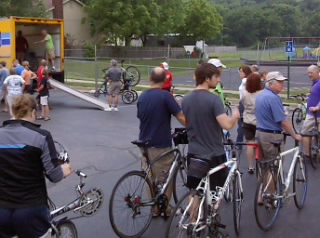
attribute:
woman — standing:
[1, 93, 72, 236]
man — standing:
[103, 58, 125, 113]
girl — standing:
[33, 70, 50, 122]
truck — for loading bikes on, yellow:
[0, 15, 66, 91]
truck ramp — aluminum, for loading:
[48, 77, 108, 111]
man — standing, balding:
[299, 64, 319, 161]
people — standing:
[134, 58, 320, 238]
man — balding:
[135, 66, 185, 220]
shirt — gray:
[105, 67, 124, 83]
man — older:
[251, 71, 303, 206]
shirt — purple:
[306, 79, 319, 117]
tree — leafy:
[83, 0, 160, 58]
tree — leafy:
[142, 0, 223, 59]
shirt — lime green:
[42, 34, 54, 51]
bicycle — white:
[166, 140, 260, 237]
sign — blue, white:
[283, 39, 295, 54]